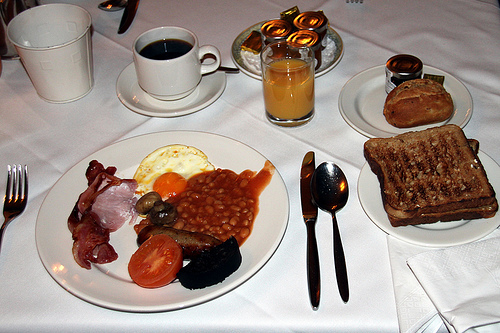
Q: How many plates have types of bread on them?
A: Two.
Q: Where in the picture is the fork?
A: Left.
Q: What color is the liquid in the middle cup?
A: Black.